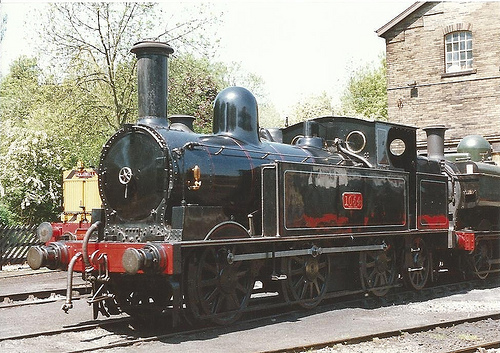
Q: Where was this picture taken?
A: At a railyard.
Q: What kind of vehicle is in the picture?
A: A train.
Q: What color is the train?
A: Black.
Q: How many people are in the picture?
A: Zero.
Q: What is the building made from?
A: Bricks.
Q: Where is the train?
A: On the tracks.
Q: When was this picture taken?
A: Day time.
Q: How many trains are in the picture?
A: One.